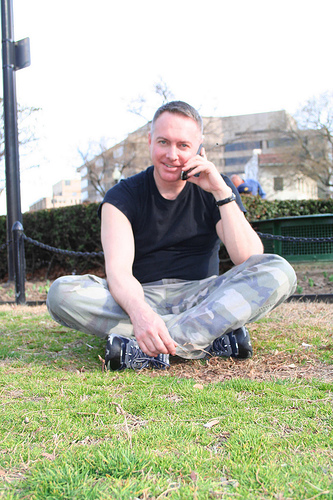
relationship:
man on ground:
[42, 100, 298, 370] [4, 288, 330, 496]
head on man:
[230, 170, 243, 182] [226, 164, 267, 196]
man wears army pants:
[42, 100, 298, 370] [42, 246, 306, 363]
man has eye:
[42, 100, 298, 370] [178, 143, 187, 146]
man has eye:
[42, 100, 298, 370] [157, 138, 166, 144]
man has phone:
[42, 100, 298, 370] [178, 143, 203, 180]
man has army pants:
[42, 100, 298, 370] [46, 254, 297, 359]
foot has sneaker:
[208, 325, 253, 361] [209, 324, 253, 360]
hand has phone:
[182, 147, 225, 194] [180, 165, 200, 179]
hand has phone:
[128, 313, 178, 358] [180, 165, 200, 179]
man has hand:
[42, 100, 298, 370] [129, 306, 177, 360]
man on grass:
[42, 100, 298, 370] [0, 301, 333, 498]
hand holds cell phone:
[179, 146, 227, 192] [181, 144, 202, 181]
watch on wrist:
[215, 191, 235, 206] [125, 305, 155, 324]